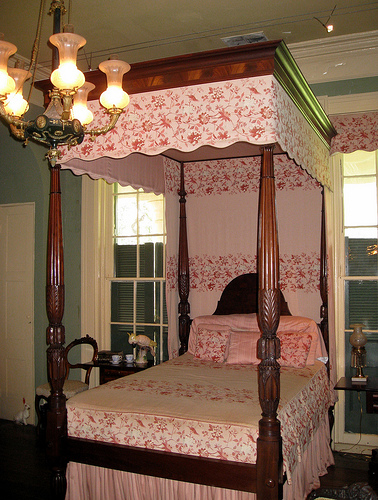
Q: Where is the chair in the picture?
A: Next to the table.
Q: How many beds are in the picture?
A: One.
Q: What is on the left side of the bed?
A: Bedside table.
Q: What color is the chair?
A: Dark wood and tan.